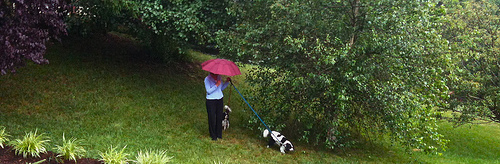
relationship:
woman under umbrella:
[204, 72, 229, 140] [202, 57, 240, 75]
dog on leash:
[258, 123, 295, 153] [230, 81, 271, 129]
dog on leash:
[258, 123, 295, 153] [225, 76, 279, 143]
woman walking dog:
[204, 72, 229, 140] [252, 112, 310, 145]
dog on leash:
[258, 123, 295, 153] [230, 84, 266, 125]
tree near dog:
[236, 2, 458, 162] [260, 125, 296, 152]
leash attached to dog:
[229, 82, 284, 143] [258, 123, 295, 153]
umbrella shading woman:
[199, 52, 244, 79] [192, 65, 235, 144]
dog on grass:
[258, 123, 295, 153] [317, 143, 489, 162]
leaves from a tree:
[279, 31, 435, 118] [80, 22, 490, 142]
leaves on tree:
[30, 46, 53, 63] [201, 5, 454, 158]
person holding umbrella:
[194, 72, 259, 133] [197, 54, 242, 85]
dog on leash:
[258, 123, 295, 153] [224, 81, 271, 128]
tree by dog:
[236, 2, 458, 162] [257, 124, 301, 156]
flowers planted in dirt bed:
[1, 120, 174, 162] [6, 141, 106, 161]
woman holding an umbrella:
[204, 72, 229, 140] [201, 56, 242, 76]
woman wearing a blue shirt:
[204, 72, 229, 140] [202, 74, 232, 101]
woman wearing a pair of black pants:
[204, 72, 229, 140] [205, 100, 230, 138]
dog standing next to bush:
[258, 123, 295, 153] [234, 7, 482, 159]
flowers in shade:
[0, 24, 62, 93] [78, 33, 188, 111]